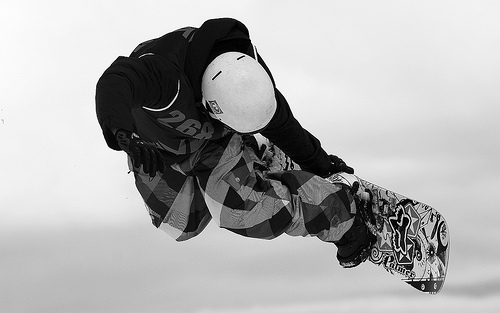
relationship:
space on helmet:
[209, 70, 223, 80] [201, 50, 278, 135]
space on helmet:
[237, 53, 247, 61] [201, 50, 278, 135]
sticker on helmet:
[207, 99, 223, 116] [201, 50, 278, 135]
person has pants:
[96, 17, 377, 269] [128, 133, 357, 244]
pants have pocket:
[128, 133, 357, 244] [223, 165, 256, 203]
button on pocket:
[235, 176, 242, 183] [223, 165, 256, 203]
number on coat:
[157, 108, 214, 143] [96, 17, 333, 174]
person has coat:
[96, 17, 377, 269] [96, 17, 333, 174]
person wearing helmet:
[96, 17, 377, 269] [201, 50, 278, 135]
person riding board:
[96, 17, 377, 269] [355, 175, 451, 296]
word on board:
[383, 254, 416, 280] [355, 175, 451, 296]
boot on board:
[337, 181, 376, 269] [355, 175, 451, 296]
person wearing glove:
[96, 17, 377, 269] [116, 130, 169, 177]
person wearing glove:
[96, 17, 377, 269] [328, 152, 357, 176]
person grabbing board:
[96, 17, 377, 269] [355, 175, 451, 296]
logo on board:
[386, 205, 412, 258] [355, 175, 451, 296]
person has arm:
[96, 17, 377, 269] [95, 53, 170, 138]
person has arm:
[96, 17, 377, 269] [262, 82, 331, 176]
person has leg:
[96, 17, 377, 269] [200, 132, 353, 240]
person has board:
[96, 17, 377, 269] [355, 175, 451, 296]